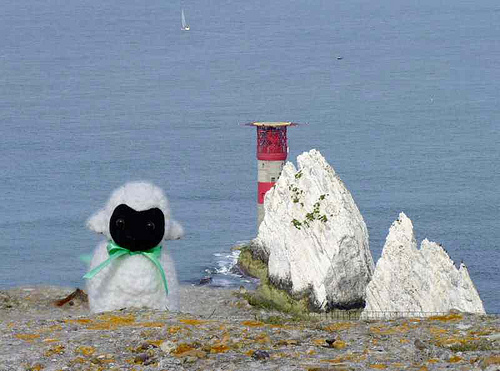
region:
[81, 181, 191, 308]
The stuffed animal sheep on the ground.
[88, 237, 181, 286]
The green ribbon around the stuffed animal's neck.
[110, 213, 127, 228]
The left eye of the stuffed animal.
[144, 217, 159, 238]
The right eye of the stuffed animal.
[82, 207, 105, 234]
The left ear of the stuffed animal.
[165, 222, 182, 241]
The right ear of the stuffed animal.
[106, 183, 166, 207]
The top of the head of the stuffed animal.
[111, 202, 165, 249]
The black color on the face of the stuffed animal.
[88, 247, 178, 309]
The body area of the stuffed animal.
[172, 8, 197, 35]
The white sailboat in the water.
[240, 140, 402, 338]
the rock is big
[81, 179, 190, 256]
the head of a stuffed animal sheep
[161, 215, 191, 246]
the ear of a stuffed animal sheep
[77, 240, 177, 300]
a green bow on the sheep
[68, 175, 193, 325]
a white and black stuffed animal sheep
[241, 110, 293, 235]
a red and white tower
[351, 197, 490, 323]
a large gray rock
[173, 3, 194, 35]
a sailboat in the water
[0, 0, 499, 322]
a large blue body of water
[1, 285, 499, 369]
a gray rocky ground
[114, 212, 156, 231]
the eyes of the sheep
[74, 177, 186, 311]
this is a sheep doll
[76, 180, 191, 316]
the sheep doll is white in color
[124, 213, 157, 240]
the face is black in color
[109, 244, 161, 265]
it has a green ribbon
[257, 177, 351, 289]
this is a rock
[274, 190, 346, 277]
the rock is painted white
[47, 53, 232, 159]
water is behind the doll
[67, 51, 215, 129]
the water is calm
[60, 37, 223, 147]
the water is blue in color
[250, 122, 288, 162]
the post is rusty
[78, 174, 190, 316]
a white stuffed sheep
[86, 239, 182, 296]
a green ribbon around a stuffed sheep's neck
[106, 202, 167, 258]
a black face on a sheep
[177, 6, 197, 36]
a white sale on the water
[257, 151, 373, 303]
a large white rock by the water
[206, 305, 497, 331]
wire holding in concrete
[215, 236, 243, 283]
white waves hitting a rock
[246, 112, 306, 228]
a red and white building warning marker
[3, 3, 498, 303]
smooth blue water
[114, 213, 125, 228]
a black plastic eye